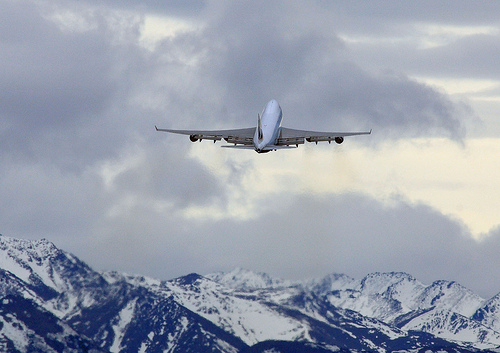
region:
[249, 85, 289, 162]
white body of plane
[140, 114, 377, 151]
grey wings on plane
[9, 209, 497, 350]
mountain range below plane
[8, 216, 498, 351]
snow on the mountains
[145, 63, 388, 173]
the plane is white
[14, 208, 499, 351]
a mountain range below plane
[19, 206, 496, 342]
snow on the mountains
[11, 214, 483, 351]
grey rock on the mountain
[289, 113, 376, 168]
right wing of plane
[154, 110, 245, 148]
left wing on plane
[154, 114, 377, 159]
planes wings are grey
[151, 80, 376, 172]
the plane is acending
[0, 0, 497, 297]
cloud cover in daytime sky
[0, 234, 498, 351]
snow patches on mountain tops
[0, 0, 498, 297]
commercial plane in cloudy sky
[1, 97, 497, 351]
commercial plane above snowy mountains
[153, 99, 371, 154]
commercial jet with white body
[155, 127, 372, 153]
jet engines under two wings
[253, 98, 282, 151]
tail on top of plane body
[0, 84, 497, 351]
a plane on top a mountain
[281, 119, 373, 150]
a wing on the right side of plane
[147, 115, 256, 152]
a wing on the left side of plane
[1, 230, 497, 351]
the picks of the mountain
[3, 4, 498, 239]
a plane in a cloudy sky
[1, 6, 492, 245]
the sky is cloudy with dark clouds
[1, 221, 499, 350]
snow over the mountain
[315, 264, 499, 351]
the snow is color white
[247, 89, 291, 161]
the body of the plane is gray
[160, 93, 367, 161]
white plane in air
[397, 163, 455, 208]
white clouds in blue sky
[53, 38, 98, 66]
white clouds in blue sky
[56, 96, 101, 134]
white clouds in blue sky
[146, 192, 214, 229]
white clouds in blue sky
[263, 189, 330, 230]
white clouds in blue sky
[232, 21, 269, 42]
white clouds in blue sky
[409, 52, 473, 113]
white clouds in blue sky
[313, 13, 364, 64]
white clouds in blue sky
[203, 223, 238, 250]
white clouds in blue sky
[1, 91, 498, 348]
plane flying over the mountain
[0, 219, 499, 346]
mountain is covered with snow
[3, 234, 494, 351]
snow covers the mountain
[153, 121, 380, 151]
the wings of a plane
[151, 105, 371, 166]
plane in the sky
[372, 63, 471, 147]
cloud in the sky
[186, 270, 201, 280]
A point of a mountain.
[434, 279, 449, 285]
A point of a mountain.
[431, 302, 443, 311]
A point of a mountain.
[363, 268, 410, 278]
A point of a mountain.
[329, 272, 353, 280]
A point of a mountain.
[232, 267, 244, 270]
A point of a mountain.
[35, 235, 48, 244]
A point of a mountain.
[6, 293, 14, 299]
A point of a mountain.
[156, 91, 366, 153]
An airplaine in the sky.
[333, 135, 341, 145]
A plane engine.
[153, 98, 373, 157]
plane is flying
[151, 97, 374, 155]
plane is in the sky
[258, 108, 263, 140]
tail is apart of plane